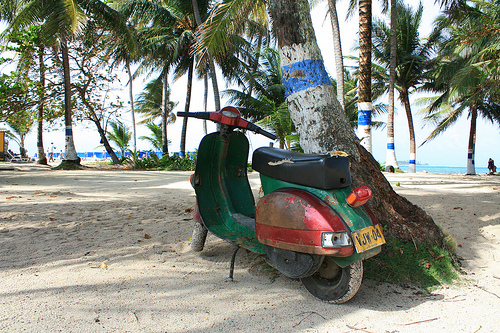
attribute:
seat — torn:
[252, 149, 348, 190]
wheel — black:
[293, 232, 367, 309]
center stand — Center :
[224, 242, 241, 284]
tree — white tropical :
[125, 75, 138, 165]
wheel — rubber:
[300, 260, 363, 305]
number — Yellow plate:
[356, 202, 381, 267]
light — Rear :
[345, 187, 375, 206]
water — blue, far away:
[404, 162, 485, 174]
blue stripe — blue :
[251, 56, 344, 95]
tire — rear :
[304, 244, 363, 305]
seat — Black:
[252, 143, 349, 195]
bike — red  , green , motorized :
[169, 99, 387, 308]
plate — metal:
[350, 227, 372, 249]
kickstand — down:
[223, 243, 243, 283]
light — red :
[335, 174, 375, 219]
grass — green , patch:
[361, 213, 463, 295]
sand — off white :
[37, 217, 151, 297]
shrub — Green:
[120, 148, 198, 171]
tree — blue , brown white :
[233, 28, 464, 255]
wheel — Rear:
[298, 252, 365, 304]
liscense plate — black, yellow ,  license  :
[348, 225, 396, 254]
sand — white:
[1, 172, 498, 332]